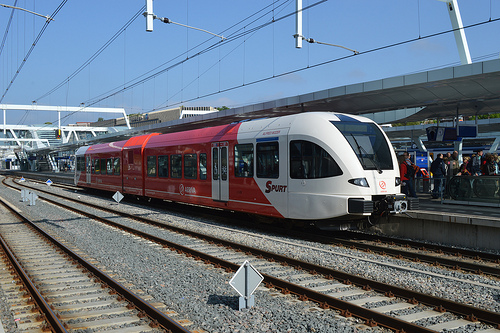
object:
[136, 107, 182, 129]
cocrete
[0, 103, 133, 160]
metal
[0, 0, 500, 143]
wires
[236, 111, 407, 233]
engine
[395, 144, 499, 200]
people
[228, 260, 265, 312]
sign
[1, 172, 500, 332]
track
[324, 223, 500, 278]
track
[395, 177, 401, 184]
train light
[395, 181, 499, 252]
platform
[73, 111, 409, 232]
short train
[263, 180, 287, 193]
word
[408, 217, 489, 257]
wall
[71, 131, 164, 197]
car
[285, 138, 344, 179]
window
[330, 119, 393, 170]
window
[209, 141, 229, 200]
door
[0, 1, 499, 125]
sky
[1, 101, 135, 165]
overpass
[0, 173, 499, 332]
gravel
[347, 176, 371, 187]
light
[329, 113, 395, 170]
windshield